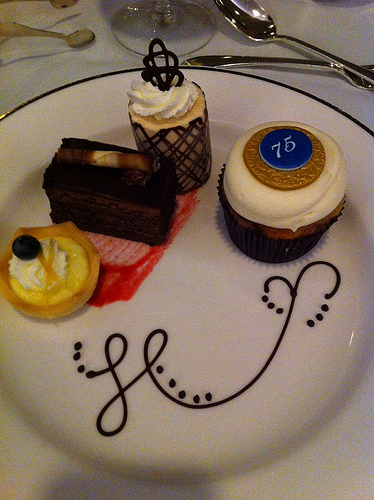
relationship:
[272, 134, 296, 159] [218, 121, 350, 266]
number on cupcake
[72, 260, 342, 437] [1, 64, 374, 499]
design on plate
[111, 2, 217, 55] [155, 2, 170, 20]
base under stem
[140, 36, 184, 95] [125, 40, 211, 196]
florish on top of pastry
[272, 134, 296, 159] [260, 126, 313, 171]
number in circle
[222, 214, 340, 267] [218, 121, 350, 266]
wrapper on cupcake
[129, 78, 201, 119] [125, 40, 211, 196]
whip cream on pastry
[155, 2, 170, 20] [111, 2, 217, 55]
stem on base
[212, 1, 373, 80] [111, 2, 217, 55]
spoon by base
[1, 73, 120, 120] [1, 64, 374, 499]
trim on plate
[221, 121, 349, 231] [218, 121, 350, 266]
frosting on cupcake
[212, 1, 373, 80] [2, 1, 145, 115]
spoon laying on tablecloth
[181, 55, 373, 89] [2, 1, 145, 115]
fork on table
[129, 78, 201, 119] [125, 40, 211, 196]
whipped cream on pastry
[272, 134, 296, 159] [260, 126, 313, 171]
number on circle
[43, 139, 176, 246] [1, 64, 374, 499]
cake on plate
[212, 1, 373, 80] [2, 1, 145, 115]
spoon on tablecloth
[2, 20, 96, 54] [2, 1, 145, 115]
spoon on tablecloth